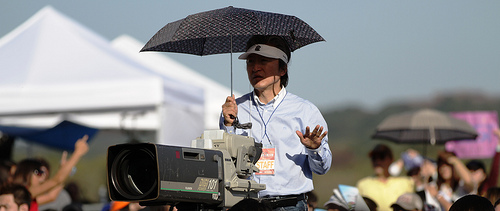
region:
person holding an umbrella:
[146, 10, 341, 210]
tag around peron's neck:
[257, 103, 277, 175]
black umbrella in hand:
[140, 3, 316, 59]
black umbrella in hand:
[360, 96, 458, 146]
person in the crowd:
[356, 140, 392, 206]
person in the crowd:
[18, 163, 49, 208]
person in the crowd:
[437, 151, 452, 207]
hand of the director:
[296, 120, 327, 162]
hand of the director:
[218, 97, 238, 127]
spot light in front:
[106, 131, 225, 206]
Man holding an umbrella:
[128, 6, 368, 191]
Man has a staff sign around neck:
[249, 124, 280, 188]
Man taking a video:
[86, 113, 211, 205]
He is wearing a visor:
[227, 21, 302, 80]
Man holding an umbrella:
[340, 71, 481, 201]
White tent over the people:
[11, 11, 201, 151]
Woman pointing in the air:
[13, 130, 142, 204]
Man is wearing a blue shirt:
[210, 85, 354, 196]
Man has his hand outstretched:
[292, 120, 347, 180]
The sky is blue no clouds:
[332, 20, 473, 87]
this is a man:
[240, 38, 321, 176]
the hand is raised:
[293, 122, 333, 152]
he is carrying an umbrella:
[208, 1, 254, 96]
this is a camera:
[101, 130, 263, 202]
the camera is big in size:
[106, 141, 221, 208]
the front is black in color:
[111, 150, 153, 193]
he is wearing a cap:
[237, 40, 283, 60]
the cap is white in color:
[262, 46, 271, 56]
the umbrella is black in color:
[221, 13, 251, 30]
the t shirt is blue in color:
[280, 100, 303, 127]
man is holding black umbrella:
[139, 5, 326, 50]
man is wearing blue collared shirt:
[209, 91, 368, 205]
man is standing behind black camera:
[108, 130, 255, 210]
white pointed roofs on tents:
[20, 0, 203, 131]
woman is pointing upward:
[10, 141, 86, 201]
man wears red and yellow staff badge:
[232, 134, 308, 200]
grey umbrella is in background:
[377, 101, 497, 152]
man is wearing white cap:
[245, 36, 287, 66]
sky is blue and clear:
[326, 42, 466, 99]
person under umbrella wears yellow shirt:
[351, 92, 476, 209]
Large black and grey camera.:
[103, 127, 266, 207]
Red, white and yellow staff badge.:
[255, 145, 275, 172]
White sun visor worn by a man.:
[235, 40, 290, 60]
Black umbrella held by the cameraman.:
[136, 5, 326, 120]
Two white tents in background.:
[0, 1, 240, 141]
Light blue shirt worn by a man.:
[220, 95, 326, 195]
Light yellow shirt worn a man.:
[355, 172, 410, 202]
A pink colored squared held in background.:
[440, 110, 498, 162]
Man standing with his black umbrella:
[140, 5, 331, 209]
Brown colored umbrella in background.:
[370, 107, 479, 171]